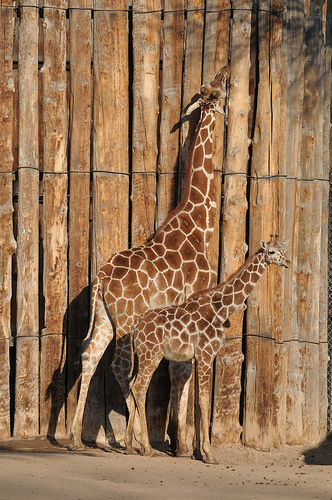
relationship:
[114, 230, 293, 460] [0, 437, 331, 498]
baby giraffe standing in dirt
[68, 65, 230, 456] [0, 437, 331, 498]
adult giraffe standing in dirt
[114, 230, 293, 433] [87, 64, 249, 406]
baby giraffe next to an giraffe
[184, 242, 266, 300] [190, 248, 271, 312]
hair along neck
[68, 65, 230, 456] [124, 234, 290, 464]
adult giraffe and baby giraffe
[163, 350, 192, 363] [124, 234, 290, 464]
belly underneath baby giraffe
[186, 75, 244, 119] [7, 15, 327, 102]
giraffe's head facing fence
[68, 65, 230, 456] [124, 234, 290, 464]
adult giraffe behind baby giraffe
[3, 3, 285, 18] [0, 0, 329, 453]
wire on fence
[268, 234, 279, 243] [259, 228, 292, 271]
horns on head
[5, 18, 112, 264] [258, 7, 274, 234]
fence made out of logs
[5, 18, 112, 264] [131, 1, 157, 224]
fence made out of logs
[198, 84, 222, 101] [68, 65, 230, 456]
horns on adult giraffe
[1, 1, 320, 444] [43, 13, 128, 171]
wall made of logs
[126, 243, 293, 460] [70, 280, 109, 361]
hair on tail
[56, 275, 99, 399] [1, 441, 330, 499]
tail hanging down towards ground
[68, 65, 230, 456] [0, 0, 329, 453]
adult giraffe standing near fence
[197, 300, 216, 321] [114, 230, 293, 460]
spots on baby giraffe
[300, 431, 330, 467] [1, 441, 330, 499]
shadow on ground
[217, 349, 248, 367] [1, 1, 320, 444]
knobs on wall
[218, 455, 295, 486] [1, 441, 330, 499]
dirt on ground